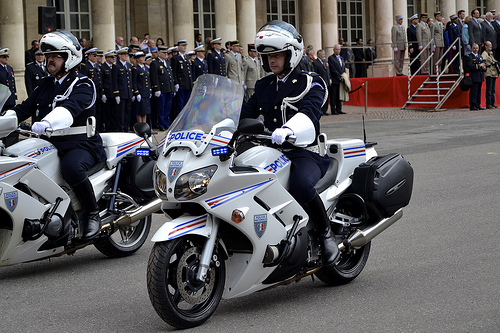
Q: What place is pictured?
A: It is a street.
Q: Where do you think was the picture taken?
A: It was taken at the street.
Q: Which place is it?
A: It is a street.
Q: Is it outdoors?
A: Yes, it is outdoors.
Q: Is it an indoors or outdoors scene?
A: It is outdoors.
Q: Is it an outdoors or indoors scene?
A: It is outdoors.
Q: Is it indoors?
A: No, it is outdoors.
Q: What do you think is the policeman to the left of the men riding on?
A: The policeman is riding on a motorcycle.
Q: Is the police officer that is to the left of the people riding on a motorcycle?
A: Yes, the policeman is riding on a motorcycle.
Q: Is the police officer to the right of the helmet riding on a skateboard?
A: No, the police officer is riding on a motorcycle.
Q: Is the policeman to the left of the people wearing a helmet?
A: Yes, the police officer is wearing a helmet.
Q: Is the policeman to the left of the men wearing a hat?
A: No, the policeman is wearing a helmet.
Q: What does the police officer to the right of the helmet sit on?
A: The policeman sits on the seat.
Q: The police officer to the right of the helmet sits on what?
A: The policeman sits on the seat.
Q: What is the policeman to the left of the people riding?
A: The police officer is riding a motorcycle.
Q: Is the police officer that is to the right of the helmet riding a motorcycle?
A: Yes, the policeman is riding a motorcycle.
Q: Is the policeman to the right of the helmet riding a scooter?
A: No, the policeman is riding a motorcycle.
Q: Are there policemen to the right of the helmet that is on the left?
A: Yes, there is a policeman to the right of the helmet.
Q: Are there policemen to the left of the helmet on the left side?
A: No, the policeman is to the right of the helmet.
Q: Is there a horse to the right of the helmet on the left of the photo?
A: No, there is a policeman to the right of the helmet.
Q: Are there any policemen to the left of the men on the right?
A: Yes, there is a policeman to the left of the men.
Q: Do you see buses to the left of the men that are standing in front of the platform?
A: No, there is a policeman to the left of the men.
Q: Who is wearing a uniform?
A: The police officer is wearing a uniform.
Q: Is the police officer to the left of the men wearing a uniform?
A: Yes, the police officer is wearing a uniform.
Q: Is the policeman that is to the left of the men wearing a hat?
A: No, the policeman is wearing a uniform.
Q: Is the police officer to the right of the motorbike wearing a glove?
A: Yes, the policeman is wearing a glove.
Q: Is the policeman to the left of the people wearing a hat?
A: No, the police officer is wearing a glove.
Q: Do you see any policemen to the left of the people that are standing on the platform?
A: Yes, there is a policeman to the left of the people.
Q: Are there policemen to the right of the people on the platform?
A: No, the policeman is to the left of the people.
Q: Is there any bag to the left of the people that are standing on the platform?
A: No, there is a policeman to the left of the people.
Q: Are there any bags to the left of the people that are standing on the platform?
A: No, there is a policeman to the left of the people.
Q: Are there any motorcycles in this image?
A: Yes, there is a motorcycle.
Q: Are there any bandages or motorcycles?
A: Yes, there is a motorcycle.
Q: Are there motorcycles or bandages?
A: Yes, there is a motorcycle.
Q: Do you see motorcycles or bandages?
A: Yes, there is a motorcycle.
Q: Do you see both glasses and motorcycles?
A: No, there is a motorcycle but no glasses.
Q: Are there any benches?
A: No, there are no benches.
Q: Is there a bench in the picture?
A: No, there are no benches.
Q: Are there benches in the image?
A: No, there are no benches.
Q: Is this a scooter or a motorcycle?
A: This is a motorcycle.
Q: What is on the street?
A: The motorbike is on the street.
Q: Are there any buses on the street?
A: No, there is a motorcycle on the street.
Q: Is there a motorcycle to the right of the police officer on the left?
A: Yes, there is a motorcycle to the right of the police officer.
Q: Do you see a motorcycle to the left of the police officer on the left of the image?
A: No, the motorcycle is to the right of the police officer.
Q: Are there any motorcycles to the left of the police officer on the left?
A: No, the motorcycle is to the right of the police officer.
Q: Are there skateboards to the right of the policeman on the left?
A: No, there is a motorcycle to the right of the police officer.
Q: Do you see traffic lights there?
A: No, there are no traffic lights.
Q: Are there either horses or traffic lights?
A: No, there are no traffic lights or horses.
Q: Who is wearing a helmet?
A: The policeman is wearing a helmet.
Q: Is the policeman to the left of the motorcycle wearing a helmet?
A: Yes, the police officer is wearing a helmet.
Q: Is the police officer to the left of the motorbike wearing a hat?
A: No, the policeman is wearing a helmet.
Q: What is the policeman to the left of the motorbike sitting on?
A: The policeman is sitting on the seat.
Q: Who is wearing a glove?
A: The policeman is wearing a glove.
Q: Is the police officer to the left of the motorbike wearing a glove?
A: Yes, the police officer is wearing a glove.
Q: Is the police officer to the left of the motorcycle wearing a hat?
A: No, the policeman is wearing a glove.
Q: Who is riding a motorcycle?
A: The police officer is riding a motorcycle.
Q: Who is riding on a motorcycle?
A: The policeman is riding on a motorcycle.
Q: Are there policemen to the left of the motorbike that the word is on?
A: Yes, there is a policeman to the left of the motorbike.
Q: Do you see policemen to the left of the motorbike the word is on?
A: Yes, there is a policeman to the left of the motorbike.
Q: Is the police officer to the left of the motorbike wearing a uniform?
A: Yes, the police officer is wearing a uniform.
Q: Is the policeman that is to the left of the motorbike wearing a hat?
A: No, the policeman is wearing a uniform.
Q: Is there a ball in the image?
A: No, there are no balls.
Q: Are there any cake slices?
A: No, there are no cake slices.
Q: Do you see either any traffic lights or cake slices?
A: No, there are no cake slices or traffic lights.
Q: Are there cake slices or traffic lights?
A: No, there are no cake slices or traffic lights.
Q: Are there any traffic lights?
A: No, there are no traffic lights.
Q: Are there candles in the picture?
A: No, there are no candles.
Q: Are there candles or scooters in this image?
A: No, there are no candles or scooters.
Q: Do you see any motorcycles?
A: Yes, there is a motorcycle.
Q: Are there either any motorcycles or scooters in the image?
A: Yes, there is a motorcycle.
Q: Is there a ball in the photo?
A: No, there are no balls.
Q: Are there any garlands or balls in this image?
A: No, there are no balls or garlands.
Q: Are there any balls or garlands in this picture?
A: No, there are no balls or garlands.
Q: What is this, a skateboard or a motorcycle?
A: This is a motorcycle.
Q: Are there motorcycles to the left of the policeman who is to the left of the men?
A: Yes, there is a motorcycle to the left of the policeman.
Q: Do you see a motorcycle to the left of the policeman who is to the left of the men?
A: Yes, there is a motorcycle to the left of the policeman.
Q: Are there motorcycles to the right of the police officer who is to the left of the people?
A: No, the motorcycle is to the left of the police officer.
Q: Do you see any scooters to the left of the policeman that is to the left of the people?
A: No, there is a motorcycle to the left of the policeman.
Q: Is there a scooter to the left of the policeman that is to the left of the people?
A: No, there is a motorcycle to the left of the policeman.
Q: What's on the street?
A: The motorbike is on the street.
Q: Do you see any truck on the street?
A: No, there is a motorcycle on the street.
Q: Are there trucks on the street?
A: No, there is a motorcycle on the street.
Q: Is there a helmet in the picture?
A: Yes, there is a helmet.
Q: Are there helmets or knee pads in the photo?
A: Yes, there is a helmet.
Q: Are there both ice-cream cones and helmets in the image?
A: No, there is a helmet but no ice-cream cones.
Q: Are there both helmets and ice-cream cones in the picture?
A: No, there is a helmet but no ice-cream cones.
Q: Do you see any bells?
A: No, there are no bells.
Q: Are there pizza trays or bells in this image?
A: No, there are no bells or pizza trays.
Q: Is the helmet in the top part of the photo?
A: Yes, the helmet is in the top of the image.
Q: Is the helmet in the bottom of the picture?
A: No, the helmet is in the top of the image.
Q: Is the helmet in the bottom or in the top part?
A: The helmet is in the top of the image.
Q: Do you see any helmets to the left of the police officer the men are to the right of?
A: Yes, there is a helmet to the left of the policeman.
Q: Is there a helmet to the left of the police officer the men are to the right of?
A: Yes, there is a helmet to the left of the policeman.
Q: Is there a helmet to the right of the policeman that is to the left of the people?
A: No, the helmet is to the left of the police officer.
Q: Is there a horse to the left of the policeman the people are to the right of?
A: No, there is a helmet to the left of the policeman.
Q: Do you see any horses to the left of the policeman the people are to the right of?
A: No, there is a helmet to the left of the policeman.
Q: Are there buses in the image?
A: No, there are no buses.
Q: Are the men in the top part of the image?
A: Yes, the men are in the top of the image.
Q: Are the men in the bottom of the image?
A: No, the men are in the top of the image.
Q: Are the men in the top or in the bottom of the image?
A: The men are in the top of the image.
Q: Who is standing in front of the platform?
A: The men are standing in front of the platform.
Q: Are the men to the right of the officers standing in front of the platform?
A: Yes, the men are standing in front of the platform.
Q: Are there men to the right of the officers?
A: Yes, there are men to the right of the officers.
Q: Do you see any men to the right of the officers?
A: Yes, there are men to the right of the officers.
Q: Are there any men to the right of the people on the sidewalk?
A: Yes, there are men to the right of the officers.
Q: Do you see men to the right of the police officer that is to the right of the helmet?
A: Yes, there are men to the right of the police officer.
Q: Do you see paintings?
A: No, there are no paintings.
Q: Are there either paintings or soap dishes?
A: No, there are no paintings or soap dishes.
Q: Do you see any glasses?
A: No, there are no glasses.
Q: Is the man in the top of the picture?
A: Yes, the man is in the top of the image.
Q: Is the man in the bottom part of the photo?
A: No, the man is in the top of the image.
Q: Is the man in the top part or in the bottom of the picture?
A: The man is in the top of the image.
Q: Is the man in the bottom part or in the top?
A: The man is in the top of the image.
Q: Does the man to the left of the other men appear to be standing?
A: Yes, the man is standing.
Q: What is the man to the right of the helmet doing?
A: The man is standing.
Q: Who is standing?
A: The man is standing.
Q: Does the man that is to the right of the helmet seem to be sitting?
A: No, the man is standing.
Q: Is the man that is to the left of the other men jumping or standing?
A: The man is standing.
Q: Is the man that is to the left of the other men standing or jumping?
A: The man is standing.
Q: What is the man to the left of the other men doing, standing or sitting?
A: The man is standing.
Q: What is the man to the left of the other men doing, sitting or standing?
A: The man is standing.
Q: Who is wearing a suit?
A: The man is wearing a suit.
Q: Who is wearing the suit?
A: The man is wearing a suit.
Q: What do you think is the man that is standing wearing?
A: The man is wearing a suit.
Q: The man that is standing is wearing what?
A: The man is wearing a suit.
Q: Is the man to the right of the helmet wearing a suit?
A: Yes, the man is wearing a suit.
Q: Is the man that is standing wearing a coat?
A: No, the man is wearing a suit.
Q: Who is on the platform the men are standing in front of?
A: The people are on the platform.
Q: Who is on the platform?
A: The people are on the platform.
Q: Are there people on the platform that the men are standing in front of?
A: Yes, there are people on the platform.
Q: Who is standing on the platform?
A: The people are standing on the platform.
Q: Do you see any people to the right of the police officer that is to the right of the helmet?
A: Yes, there are people to the right of the police officer.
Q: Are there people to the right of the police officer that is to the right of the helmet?
A: Yes, there are people to the right of the police officer.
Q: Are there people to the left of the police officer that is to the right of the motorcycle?
A: No, the people are to the right of the policeman.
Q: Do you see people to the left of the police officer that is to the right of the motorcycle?
A: No, the people are to the right of the policeman.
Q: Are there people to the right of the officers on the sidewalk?
A: Yes, there are people to the right of the officers.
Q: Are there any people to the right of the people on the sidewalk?
A: Yes, there are people to the right of the officers.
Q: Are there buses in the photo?
A: No, there are no buses.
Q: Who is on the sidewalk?
A: The officers are on the sidewalk.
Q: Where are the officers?
A: The officers are on the sidewalk.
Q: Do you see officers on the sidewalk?
A: Yes, there are officers on the sidewalk.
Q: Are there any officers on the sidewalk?
A: Yes, there are officers on the sidewalk.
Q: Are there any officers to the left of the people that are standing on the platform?
A: Yes, there are officers to the left of the people.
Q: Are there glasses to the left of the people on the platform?
A: No, there are officers to the left of the people.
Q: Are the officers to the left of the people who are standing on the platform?
A: Yes, the officers are to the left of the people.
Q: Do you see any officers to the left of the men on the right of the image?
A: Yes, there are officers to the left of the men.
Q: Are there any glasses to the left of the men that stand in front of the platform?
A: No, there are officers to the left of the men.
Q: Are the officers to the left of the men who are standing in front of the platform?
A: Yes, the officers are to the left of the men.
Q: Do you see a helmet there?
A: Yes, there is a helmet.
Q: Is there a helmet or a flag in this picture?
A: Yes, there is a helmet.